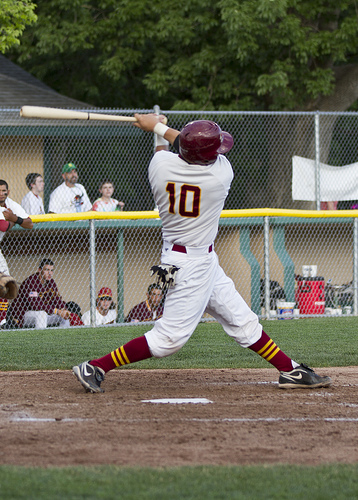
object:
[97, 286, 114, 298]
cap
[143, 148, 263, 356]
uniform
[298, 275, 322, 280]
black lid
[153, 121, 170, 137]
wristband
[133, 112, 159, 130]
hand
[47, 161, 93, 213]
man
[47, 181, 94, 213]
white t-shirt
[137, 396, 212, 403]
plate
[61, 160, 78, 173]
green cap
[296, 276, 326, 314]
cooler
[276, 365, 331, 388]
baseball cleat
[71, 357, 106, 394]
baseball cleat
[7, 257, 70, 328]
players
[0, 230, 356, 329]
dugout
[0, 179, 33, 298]
spectators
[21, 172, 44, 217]
spectators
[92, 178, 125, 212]
spectators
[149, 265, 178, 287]
gloves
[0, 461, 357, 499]
grass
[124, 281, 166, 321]
player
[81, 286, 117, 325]
player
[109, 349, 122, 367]
yellow stripes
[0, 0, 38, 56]
tree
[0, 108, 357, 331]
fence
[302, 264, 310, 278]
cups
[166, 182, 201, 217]
10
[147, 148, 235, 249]
jersey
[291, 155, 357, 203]
banner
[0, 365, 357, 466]
dirt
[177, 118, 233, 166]
helmet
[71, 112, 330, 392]
man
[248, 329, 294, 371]
red sock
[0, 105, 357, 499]
baseball game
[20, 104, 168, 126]
baseball bat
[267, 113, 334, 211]
trunk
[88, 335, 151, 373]
sock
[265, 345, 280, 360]
stripes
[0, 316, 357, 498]
baseball field